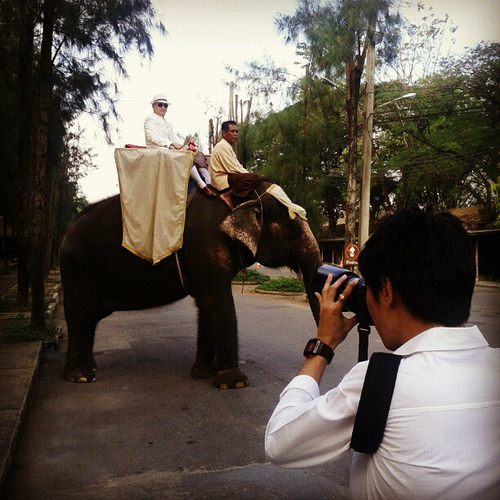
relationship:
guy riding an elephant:
[144, 92, 215, 197] [47, 160, 352, 400]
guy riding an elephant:
[207, 118, 257, 194] [47, 160, 352, 400]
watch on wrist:
[302, 337, 336, 363] [276, 305, 382, 405]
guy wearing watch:
[291, 204, 500, 488] [267, 329, 379, 372]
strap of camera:
[358, 325, 372, 362] [307, 255, 368, 313]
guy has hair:
[207, 118, 257, 194] [219, 117, 238, 132]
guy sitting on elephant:
[207, 118, 257, 194] [54, 173, 334, 392]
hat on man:
[150, 92, 172, 109] [132, 93, 217, 194]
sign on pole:
[344, 242, 362, 267] [351, 2, 380, 362]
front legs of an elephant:
[186, 265, 254, 389] [54, 173, 334, 392]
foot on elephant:
[214, 370, 249, 390] [54, 173, 334, 392]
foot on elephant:
[191, 367, 217, 379] [54, 173, 334, 392]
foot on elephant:
[63, 366, 97, 380] [54, 173, 334, 392]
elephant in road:
[54, 173, 334, 392] [38, 395, 254, 497]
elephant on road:
[54, 173, 334, 392] [46, 244, 492, 499]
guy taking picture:
[291, 204, 500, 488] [24, 77, 357, 407]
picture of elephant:
[24, 77, 357, 407] [47, 160, 352, 400]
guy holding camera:
[291, 204, 500, 488] [301, 255, 374, 341]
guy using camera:
[291, 237, 495, 488] [252, 264, 378, 338]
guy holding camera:
[291, 204, 500, 488] [308, 255, 375, 327]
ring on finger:
[336, 289, 347, 301] [334, 273, 363, 306]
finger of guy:
[334, 273, 363, 306] [291, 204, 500, 488]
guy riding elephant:
[144, 92, 215, 197] [54, 173, 334, 392]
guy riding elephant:
[207, 118, 257, 194] [54, 173, 334, 392]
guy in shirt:
[291, 204, 500, 488] [265, 323, 500, 499]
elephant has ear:
[54, 173, 334, 392] [213, 183, 281, 279]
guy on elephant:
[135, 92, 214, 212] [47, 160, 352, 400]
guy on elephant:
[207, 110, 257, 200] [47, 160, 352, 400]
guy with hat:
[291, 204, 500, 488] [137, 79, 183, 108]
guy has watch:
[291, 204, 500, 488] [302, 338, 334, 362]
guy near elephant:
[291, 204, 500, 488] [54, 173, 334, 392]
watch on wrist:
[302, 337, 336, 363] [294, 335, 339, 387]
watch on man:
[302, 337, 336, 363] [296, 239, 494, 486]